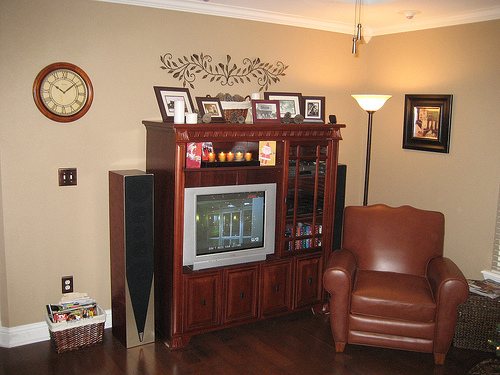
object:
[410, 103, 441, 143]
picture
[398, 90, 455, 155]
frame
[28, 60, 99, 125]
frame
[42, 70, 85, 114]
face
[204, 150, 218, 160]
candles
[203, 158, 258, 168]
tray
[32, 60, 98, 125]
clock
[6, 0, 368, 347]
wall